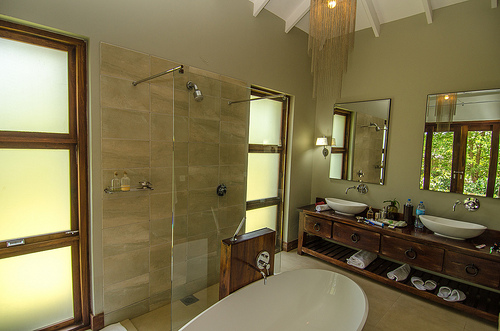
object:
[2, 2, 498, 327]
bathroom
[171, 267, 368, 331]
tub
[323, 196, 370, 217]
sinks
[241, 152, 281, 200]
window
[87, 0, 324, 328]
wall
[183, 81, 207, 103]
shower head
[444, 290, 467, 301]
slippers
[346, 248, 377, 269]
towels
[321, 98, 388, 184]
mirrors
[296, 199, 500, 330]
table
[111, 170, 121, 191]
bottle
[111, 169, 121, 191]
shampoo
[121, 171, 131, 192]
bottle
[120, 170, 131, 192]
conditioner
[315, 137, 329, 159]
sconce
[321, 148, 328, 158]
shade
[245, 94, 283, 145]
glass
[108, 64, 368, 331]
shower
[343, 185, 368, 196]
faucet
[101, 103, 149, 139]
panels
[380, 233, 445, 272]
drawer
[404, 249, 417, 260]
handle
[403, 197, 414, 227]
toiletries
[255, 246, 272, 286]
faucet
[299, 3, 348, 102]
light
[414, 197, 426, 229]
bottle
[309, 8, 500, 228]
wall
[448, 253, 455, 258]
wood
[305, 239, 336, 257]
shelf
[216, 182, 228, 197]
fixtures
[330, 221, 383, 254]
vanity